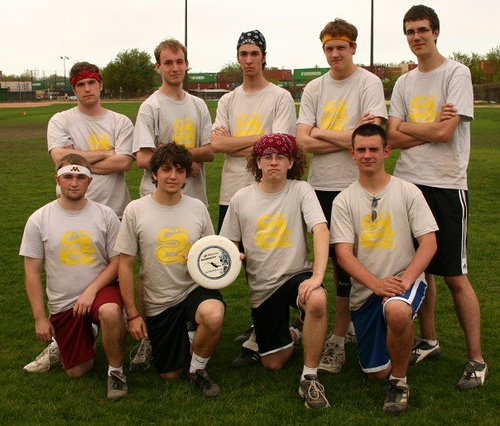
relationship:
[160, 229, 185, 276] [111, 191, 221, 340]
snake on shirt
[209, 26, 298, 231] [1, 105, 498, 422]
player on large field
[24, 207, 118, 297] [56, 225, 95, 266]
white t-shirt behind logo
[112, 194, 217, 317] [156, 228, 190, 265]
white t-shirt behind snake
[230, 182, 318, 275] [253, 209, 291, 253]
white t-shirt behind logo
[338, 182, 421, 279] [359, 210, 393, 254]
white t-shirt behind logo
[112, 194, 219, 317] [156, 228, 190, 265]
white t-shirt with snake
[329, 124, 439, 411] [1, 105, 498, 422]
man on large field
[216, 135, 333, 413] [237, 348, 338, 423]
man on field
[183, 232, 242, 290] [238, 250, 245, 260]
frisbe in hand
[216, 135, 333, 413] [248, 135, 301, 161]
man wearing bandana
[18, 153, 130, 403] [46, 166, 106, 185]
man wearing headband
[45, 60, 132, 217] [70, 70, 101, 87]
boy wearing bandana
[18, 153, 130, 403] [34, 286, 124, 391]
man wearing shorts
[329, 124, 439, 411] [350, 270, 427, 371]
man wearing blue shorts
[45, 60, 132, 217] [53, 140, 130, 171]
boy has arms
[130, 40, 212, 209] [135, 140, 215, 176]
boy has arms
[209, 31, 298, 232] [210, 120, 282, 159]
player has arms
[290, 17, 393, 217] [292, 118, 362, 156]
boy has arms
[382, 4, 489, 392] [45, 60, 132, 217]
man has boy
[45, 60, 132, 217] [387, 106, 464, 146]
boy has arms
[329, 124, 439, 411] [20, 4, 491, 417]
man part of a group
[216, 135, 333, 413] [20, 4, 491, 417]
man part of a group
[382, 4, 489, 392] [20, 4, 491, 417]
man part of a group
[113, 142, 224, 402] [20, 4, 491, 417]
man part of a group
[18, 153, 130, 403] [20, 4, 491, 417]
man part of a group